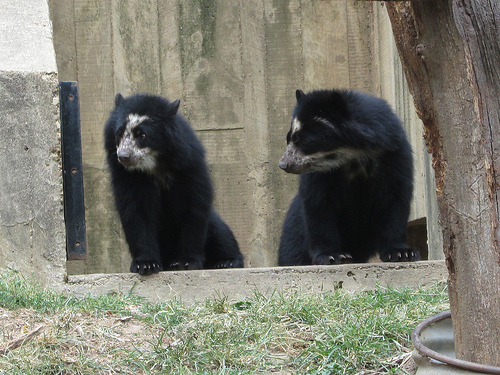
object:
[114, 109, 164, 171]
face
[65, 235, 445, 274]
ledge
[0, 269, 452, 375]
grass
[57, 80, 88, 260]
metal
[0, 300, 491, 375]
ground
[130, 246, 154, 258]
furry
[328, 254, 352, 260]
animal paws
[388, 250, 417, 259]
animal paws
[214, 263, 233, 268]
animal paws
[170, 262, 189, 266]
animal paws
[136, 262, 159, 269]
animal paws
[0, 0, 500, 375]
picture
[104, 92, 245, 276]
animal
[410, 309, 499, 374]
metal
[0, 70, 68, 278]
pillar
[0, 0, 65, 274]
wall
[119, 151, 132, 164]
nose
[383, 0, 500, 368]
tree trunk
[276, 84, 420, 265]
animal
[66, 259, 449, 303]
concrete wall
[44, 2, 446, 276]
door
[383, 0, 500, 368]
trunk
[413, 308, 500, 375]
ring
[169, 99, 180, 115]
bear's ear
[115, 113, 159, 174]
patch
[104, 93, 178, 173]
hair